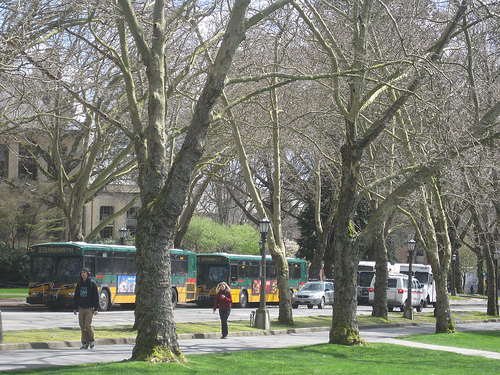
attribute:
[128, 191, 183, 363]
tree trunk — brown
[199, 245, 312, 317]
buses — green, yellow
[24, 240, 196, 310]
bus — parked, green, yellow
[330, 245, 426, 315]
van — white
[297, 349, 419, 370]
grass — green, short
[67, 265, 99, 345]
man — walking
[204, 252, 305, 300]
bus — parked, green, yellow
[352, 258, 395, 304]
bus — parked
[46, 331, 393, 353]
sidewalk — gray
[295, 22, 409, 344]
tree — brown, branchy, big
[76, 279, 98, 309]
jacket — blue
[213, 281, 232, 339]
woman — walking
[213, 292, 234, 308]
jacket — red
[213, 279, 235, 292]
hair — long, blonde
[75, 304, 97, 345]
pants — khaki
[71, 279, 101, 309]
sweater — black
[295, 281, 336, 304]
car — grey, silver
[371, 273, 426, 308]
van — white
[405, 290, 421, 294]
stripe — black, red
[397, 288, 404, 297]
light — red, on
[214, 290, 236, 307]
sweater — red